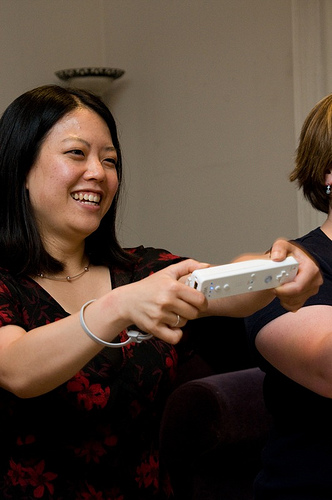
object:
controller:
[185, 254, 300, 302]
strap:
[78, 298, 132, 347]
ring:
[173, 314, 180, 327]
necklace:
[32, 226, 86, 278]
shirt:
[0, 243, 191, 500]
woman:
[0, 83, 325, 500]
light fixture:
[53, 66, 126, 97]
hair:
[0, 83, 140, 310]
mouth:
[70, 187, 105, 213]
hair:
[287, 93, 331, 215]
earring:
[324, 183, 331, 194]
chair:
[157, 363, 270, 499]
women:
[243, 90, 331, 500]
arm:
[0, 283, 132, 400]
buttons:
[214, 284, 222, 293]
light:
[209, 285, 215, 293]